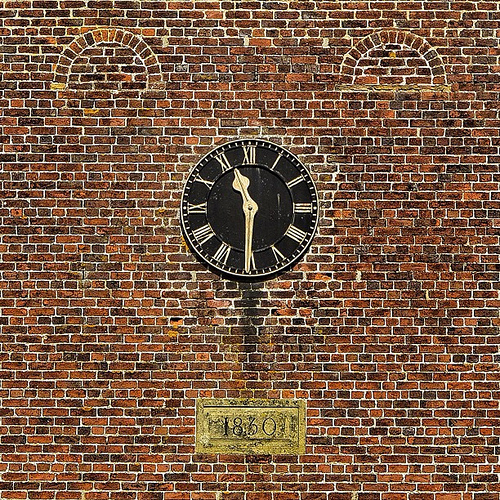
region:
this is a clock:
[172, 133, 330, 290]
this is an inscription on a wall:
[166, 364, 322, 476]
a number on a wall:
[277, 214, 315, 253]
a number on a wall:
[288, 195, 320, 222]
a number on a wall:
[279, 157, 314, 197]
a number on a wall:
[235, 129, 258, 177]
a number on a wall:
[203, 144, 236, 186]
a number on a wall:
[168, 190, 213, 222]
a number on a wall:
[175, 210, 215, 253]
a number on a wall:
[207, 244, 243, 280]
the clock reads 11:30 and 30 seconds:
[176, 129, 326, 288]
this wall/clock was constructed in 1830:
[191, 390, 313, 458]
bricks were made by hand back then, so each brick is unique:
[24, 327, 174, 456]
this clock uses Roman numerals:
[174, 125, 324, 287]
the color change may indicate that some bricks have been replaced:
[146, 110, 353, 343]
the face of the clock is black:
[173, 127, 323, 283]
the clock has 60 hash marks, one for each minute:
[175, 130, 325, 283]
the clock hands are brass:
[228, 163, 260, 274]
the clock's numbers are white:
[175, 132, 323, 284]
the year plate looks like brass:
[191, 392, 311, 457]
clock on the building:
[173, 135, 332, 283]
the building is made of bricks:
[359, 260, 473, 410]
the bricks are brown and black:
[332, 272, 487, 413]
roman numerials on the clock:
[267, 227, 308, 262]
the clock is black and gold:
[179, 140, 328, 292]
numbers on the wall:
[211, 415, 294, 442]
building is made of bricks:
[367, 272, 477, 402]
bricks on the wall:
[342, 275, 487, 417]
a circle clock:
[177, 145, 330, 285]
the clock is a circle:
[178, 136, 330, 286]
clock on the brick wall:
[162, 120, 339, 297]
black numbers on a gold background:
[218, 408, 282, 440]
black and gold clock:
[174, 128, 324, 289]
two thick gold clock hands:
[228, 170, 268, 272]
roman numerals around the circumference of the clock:
[180, 131, 325, 286]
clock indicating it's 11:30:
[176, 129, 337, 287]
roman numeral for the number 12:
[238, 142, 264, 169]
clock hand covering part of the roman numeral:
[240, 250, 259, 273]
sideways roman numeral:
[288, 196, 314, 216]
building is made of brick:
[0, 3, 499, 498]